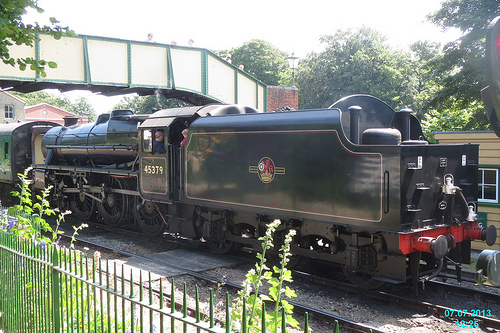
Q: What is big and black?
A: A train.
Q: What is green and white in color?
A: Footbridge.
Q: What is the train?
A: Black and green.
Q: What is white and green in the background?
A: Footbridge.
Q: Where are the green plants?
A: By fence.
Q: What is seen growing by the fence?
A: Weeds.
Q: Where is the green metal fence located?
A: Beside the train tracks.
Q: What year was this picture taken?
A: 2013.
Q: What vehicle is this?
A: Train.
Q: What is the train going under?
A: Bridge.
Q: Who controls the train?
A: Conductor.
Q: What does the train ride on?
A: Tracks.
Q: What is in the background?
A: Trees.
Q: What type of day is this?
A: Sunny.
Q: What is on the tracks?
A: A locomotive.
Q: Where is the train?
A: On the tracks.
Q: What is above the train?
A: A bridge.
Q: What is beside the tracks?
A: Railings.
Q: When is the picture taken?
A: Daytime.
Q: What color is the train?
A: Black.